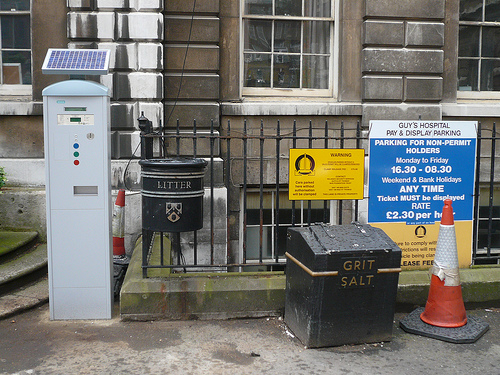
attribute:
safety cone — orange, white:
[401, 197, 495, 346]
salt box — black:
[278, 217, 402, 352]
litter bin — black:
[137, 153, 210, 235]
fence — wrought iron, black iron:
[136, 114, 499, 279]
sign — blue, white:
[366, 118, 479, 266]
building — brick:
[0, 1, 499, 267]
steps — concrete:
[1, 228, 48, 319]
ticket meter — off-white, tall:
[38, 44, 117, 322]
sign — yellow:
[289, 145, 366, 202]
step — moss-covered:
[0, 231, 36, 261]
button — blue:
[72, 140, 81, 150]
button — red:
[72, 158, 80, 166]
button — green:
[73, 150, 80, 160]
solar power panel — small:
[40, 47, 111, 77]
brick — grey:
[364, 1, 440, 123]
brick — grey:
[406, 21, 444, 45]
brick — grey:
[366, 21, 405, 45]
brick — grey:
[364, 47, 445, 75]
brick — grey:
[363, 76, 403, 102]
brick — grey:
[404, 74, 444, 103]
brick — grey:
[363, 2, 446, 19]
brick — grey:
[364, 101, 442, 123]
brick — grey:
[177, 228, 227, 266]